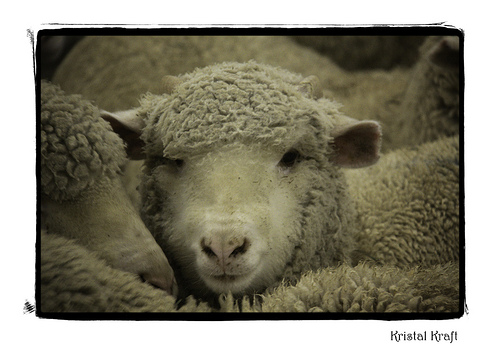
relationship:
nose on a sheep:
[192, 234, 246, 272] [104, 75, 458, 296]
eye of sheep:
[279, 143, 322, 173] [104, 75, 458, 296]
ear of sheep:
[321, 101, 386, 175] [112, 63, 455, 306]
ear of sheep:
[108, 94, 148, 164] [112, 63, 455, 306]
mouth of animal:
[189, 254, 265, 293] [100, 60, 382, 309]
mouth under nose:
[189, 254, 265, 293] [193, 230, 256, 273]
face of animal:
[152, 132, 315, 293] [100, 60, 382, 309]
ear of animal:
[100, 107, 148, 143] [100, 60, 382, 309]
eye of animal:
[274, 143, 310, 172] [100, 60, 382, 309]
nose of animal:
[197, 228, 252, 269] [100, 60, 382, 309]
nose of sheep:
[197, 228, 252, 269] [112, 63, 455, 306]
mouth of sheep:
[193, 261, 251, 286] [112, 63, 455, 306]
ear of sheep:
[321, 112, 382, 169] [112, 63, 455, 306]